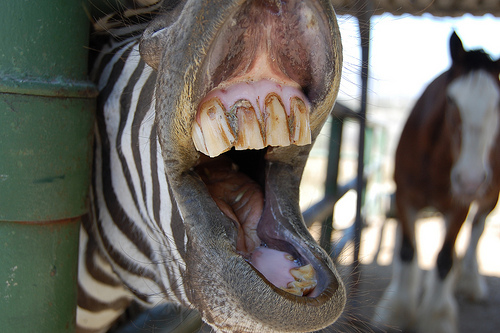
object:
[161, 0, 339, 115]
lip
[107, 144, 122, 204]
white stripe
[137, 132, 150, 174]
white stripe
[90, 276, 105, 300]
white stripe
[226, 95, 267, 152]
tooth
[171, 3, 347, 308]
mouth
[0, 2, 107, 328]
bar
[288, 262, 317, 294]
bottom teeth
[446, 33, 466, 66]
ear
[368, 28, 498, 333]
horse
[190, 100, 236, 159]
zebra tooth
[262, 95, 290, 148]
zebra tooth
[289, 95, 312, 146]
zebra tooth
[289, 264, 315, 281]
zebra tooth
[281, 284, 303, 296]
zebra tooth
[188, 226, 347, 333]
lip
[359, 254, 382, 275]
ground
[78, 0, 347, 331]
zebra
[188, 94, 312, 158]
teeth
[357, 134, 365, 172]
bar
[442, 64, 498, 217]
face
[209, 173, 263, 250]
tongue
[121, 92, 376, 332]
fence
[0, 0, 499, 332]
stable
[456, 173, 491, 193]
nose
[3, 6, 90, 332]
building